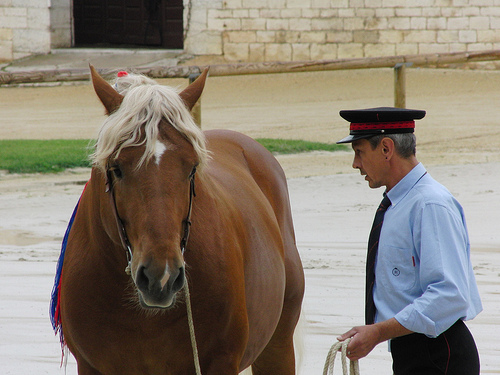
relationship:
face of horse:
[100, 95, 211, 307] [44, 59, 315, 372]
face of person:
[349, 143, 388, 188] [339, 105, 486, 373]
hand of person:
[336, 325, 382, 364] [339, 105, 486, 373]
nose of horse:
[135, 256, 187, 310] [44, 59, 315, 372]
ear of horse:
[87, 63, 127, 114] [44, 59, 315, 372]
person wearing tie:
[339, 105, 486, 373] [364, 195, 396, 336]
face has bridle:
[100, 95, 211, 307] [105, 157, 202, 267]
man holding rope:
[339, 105, 486, 373] [324, 334, 357, 374]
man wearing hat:
[339, 105, 486, 373] [333, 105, 430, 146]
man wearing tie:
[339, 105, 486, 373] [364, 195, 396, 336]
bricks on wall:
[184, 4, 328, 61] [181, 1, 499, 61]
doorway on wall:
[71, 2, 185, 48] [3, 0, 497, 70]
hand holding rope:
[336, 325, 382, 364] [324, 334, 357, 374]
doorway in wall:
[71, 2, 185, 48] [3, 0, 497, 70]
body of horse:
[55, 128, 322, 374] [44, 59, 315, 372]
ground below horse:
[0, 161, 499, 374] [44, 59, 315, 372]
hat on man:
[333, 105, 430, 146] [339, 105, 486, 373]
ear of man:
[380, 137, 398, 163] [339, 105, 486, 373]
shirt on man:
[349, 163, 483, 346] [339, 105, 486, 373]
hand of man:
[336, 325, 382, 364] [339, 105, 486, 373]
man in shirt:
[339, 105, 486, 373] [349, 163, 483, 346]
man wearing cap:
[339, 105, 486, 373] [333, 105, 430, 146]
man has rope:
[339, 105, 486, 373] [173, 258, 357, 374]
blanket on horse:
[49, 166, 97, 369] [44, 59, 315, 372]